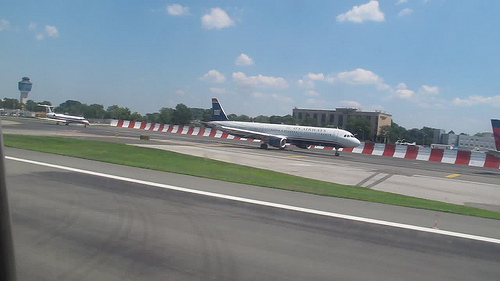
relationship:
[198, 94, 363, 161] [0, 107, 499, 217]
plane on runway